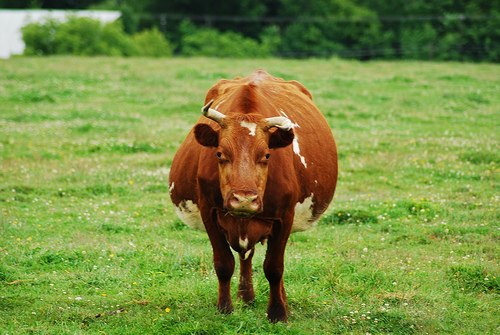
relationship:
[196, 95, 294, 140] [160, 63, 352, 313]
horn on cow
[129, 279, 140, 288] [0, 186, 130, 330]
flower on grass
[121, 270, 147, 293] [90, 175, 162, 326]
flower on ground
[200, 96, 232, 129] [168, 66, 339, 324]
horn on bull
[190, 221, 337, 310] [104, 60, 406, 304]
legs of bull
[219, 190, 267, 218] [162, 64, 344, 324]
snout of bull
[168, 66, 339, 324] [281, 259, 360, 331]
bull on grass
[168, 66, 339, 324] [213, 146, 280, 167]
bull has eyes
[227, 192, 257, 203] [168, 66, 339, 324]
nose on bull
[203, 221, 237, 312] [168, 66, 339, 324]
legs of bull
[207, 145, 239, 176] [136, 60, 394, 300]
eye of cow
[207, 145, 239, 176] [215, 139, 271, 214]
eye on face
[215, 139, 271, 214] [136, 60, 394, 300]
face of cow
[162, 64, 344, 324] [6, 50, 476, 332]
bull in field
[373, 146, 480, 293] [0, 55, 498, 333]
grass growing on ground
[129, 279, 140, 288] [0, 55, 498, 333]
flower on ground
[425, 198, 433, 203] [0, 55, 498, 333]
yellow flower on ground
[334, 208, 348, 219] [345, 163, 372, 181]
flower on ground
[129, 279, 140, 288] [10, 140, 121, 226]
flower on grass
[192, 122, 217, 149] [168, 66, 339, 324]
ear on bull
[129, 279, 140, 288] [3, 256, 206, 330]
flower on ground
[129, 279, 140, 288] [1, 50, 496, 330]
flower on grass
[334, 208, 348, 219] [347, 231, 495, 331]
flower on grass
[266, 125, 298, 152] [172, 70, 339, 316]
ear on cow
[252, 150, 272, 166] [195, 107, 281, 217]
eye on face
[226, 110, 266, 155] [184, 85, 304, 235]
spot on head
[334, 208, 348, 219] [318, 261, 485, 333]
flower in grass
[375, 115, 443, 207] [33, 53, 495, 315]
flower on ground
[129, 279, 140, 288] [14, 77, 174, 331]
flower on grass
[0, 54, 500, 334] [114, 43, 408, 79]
grass growing in background